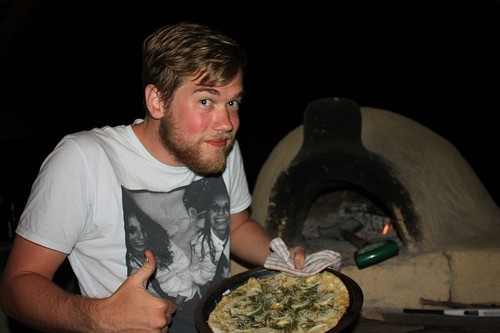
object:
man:
[2, 16, 307, 333]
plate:
[193, 259, 367, 332]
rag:
[263, 235, 341, 279]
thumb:
[130, 250, 159, 285]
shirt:
[15, 122, 255, 333]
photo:
[122, 174, 234, 303]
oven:
[249, 89, 500, 257]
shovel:
[317, 218, 370, 250]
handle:
[351, 236, 400, 272]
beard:
[157, 114, 236, 178]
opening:
[266, 94, 424, 249]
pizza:
[209, 271, 351, 333]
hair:
[140, 18, 247, 89]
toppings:
[252, 292, 273, 313]